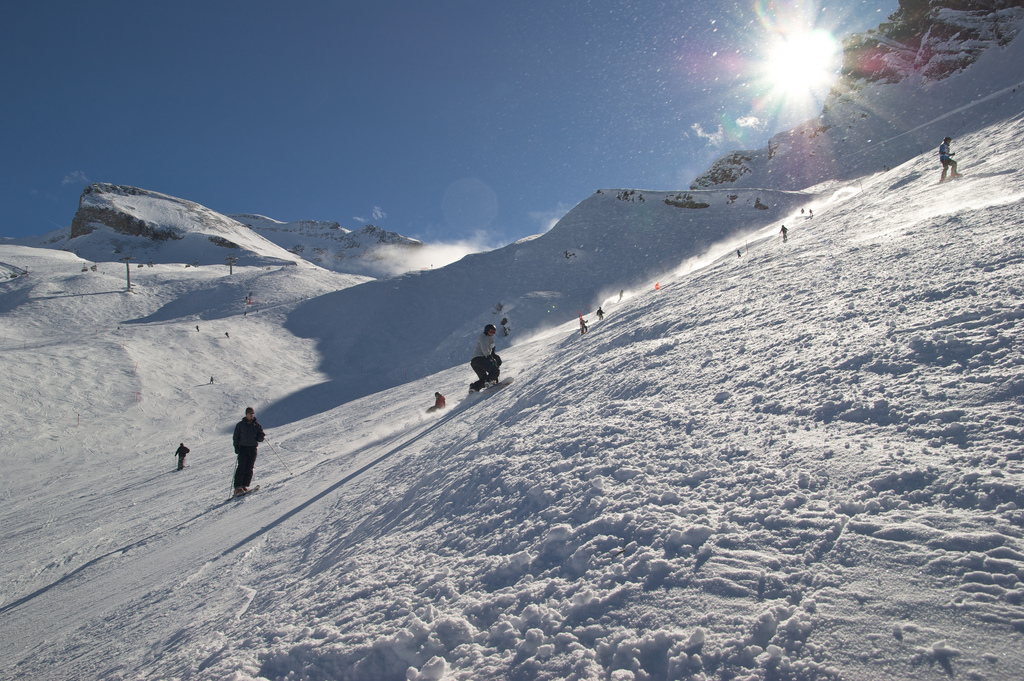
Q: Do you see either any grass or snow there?
A: Yes, there is snow.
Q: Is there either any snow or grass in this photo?
A: Yes, there is snow.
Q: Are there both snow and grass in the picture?
A: No, there is snow but no grass.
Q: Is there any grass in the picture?
A: No, there is no grass.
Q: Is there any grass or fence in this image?
A: No, there are no grass or fences.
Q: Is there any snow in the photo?
A: Yes, there is snow.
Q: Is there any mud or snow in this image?
A: Yes, there is snow.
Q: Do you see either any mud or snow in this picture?
A: Yes, there is snow.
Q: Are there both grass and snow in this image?
A: No, there is snow but no grass.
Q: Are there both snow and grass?
A: No, there is snow but no grass.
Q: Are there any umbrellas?
A: No, there are no umbrellas.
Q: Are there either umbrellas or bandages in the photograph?
A: No, there are no umbrellas or bandages.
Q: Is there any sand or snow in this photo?
A: Yes, there is snow.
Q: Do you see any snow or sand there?
A: Yes, there is snow.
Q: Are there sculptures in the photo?
A: No, there are no sculptures.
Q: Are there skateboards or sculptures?
A: No, there are no sculptures or skateboards.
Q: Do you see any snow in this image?
A: Yes, there is snow.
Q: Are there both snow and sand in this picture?
A: No, there is snow but no sand.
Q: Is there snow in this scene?
A: Yes, there is snow.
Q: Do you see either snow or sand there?
A: Yes, there is snow.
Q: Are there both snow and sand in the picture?
A: No, there is snow but no sand.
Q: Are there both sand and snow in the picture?
A: No, there is snow but no sand.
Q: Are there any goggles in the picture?
A: No, there are no goggles.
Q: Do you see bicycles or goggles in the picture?
A: No, there are no goggles or bicycles.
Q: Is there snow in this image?
A: Yes, there is snow.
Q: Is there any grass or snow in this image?
A: Yes, there is snow.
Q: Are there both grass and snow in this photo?
A: No, there is snow but no grass.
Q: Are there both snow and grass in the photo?
A: No, there is snow but no grass.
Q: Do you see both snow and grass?
A: No, there is snow but no grass.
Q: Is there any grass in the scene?
A: No, there is no grass.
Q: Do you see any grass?
A: No, there is no grass.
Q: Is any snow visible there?
A: Yes, there is snow.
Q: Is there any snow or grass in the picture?
A: Yes, there is snow.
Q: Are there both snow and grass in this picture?
A: No, there is snow but no grass.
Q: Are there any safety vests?
A: No, there are no safety vests.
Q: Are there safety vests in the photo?
A: No, there are no safety vests.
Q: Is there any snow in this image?
A: Yes, there is snow.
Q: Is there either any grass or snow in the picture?
A: Yes, there is snow.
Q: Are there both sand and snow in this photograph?
A: No, there is snow but no sand.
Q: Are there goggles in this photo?
A: No, there are no goggles.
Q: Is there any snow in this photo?
A: Yes, there is snow.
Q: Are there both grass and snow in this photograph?
A: No, there is snow but no grass.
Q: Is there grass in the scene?
A: No, there is no grass.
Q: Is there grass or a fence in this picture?
A: No, there are no grass or fences.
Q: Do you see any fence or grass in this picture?
A: No, there are no grass or fences.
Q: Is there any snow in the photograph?
A: Yes, there is snow.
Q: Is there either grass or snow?
A: Yes, there is snow.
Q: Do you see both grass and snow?
A: No, there is snow but no grass.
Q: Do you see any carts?
A: No, there are no carts.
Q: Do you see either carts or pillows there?
A: No, there are no carts or pillows.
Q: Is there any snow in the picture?
A: Yes, there is snow.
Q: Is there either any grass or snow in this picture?
A: Yes, there is snow.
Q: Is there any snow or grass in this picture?
A: Yes, there is snow.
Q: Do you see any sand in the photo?
A: No, there is no sand.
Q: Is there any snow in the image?
A: Yes, there is snow.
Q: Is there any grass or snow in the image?
A: Yes, there is snow.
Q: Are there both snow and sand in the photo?
A: No, there is snow but no sand.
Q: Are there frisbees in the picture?
A: No, there are no frisbees.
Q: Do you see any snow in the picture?
A: Yes, there is snow.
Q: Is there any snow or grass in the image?
A: Yes, there is snow.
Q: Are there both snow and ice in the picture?
A: No, there is snow but no ice.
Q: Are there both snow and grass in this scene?
A: No, there is snow but no grass.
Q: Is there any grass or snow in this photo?
A: Yes, there is snow.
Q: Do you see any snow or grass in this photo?
A: Yes, there is snow.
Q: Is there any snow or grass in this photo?
A: Yes, there is snow.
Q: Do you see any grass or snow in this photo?
A: Yes, there is snow.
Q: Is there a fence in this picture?
A: No, there are no fences.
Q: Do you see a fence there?
A: No, there are no fences.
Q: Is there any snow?
A: Yes, there is snow.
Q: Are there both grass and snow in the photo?
A: No, there is snow but no grass.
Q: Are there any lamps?
A: No, there are no lamps.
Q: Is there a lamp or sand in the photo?
A: No, there are no lamps or sand.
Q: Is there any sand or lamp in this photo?
A: No, there are no lamps or sand.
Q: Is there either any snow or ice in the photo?
A: Yes, there is snow.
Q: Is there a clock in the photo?
A: No, there are no clocks.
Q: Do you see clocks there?
A: No, there are no clocks.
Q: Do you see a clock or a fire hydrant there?
A: No, there are no clocks or fire hydrants.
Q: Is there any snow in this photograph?
A: Yes, there is snow.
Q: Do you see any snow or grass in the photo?
A: Yes, there is snow.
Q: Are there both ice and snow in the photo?
A: No, there is snow but no ice.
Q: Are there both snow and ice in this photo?
A: No, there is snow but no ice.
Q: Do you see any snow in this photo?
A: Yes, there is snow.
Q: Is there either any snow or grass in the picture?
A: Yes, there is snow.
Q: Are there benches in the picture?
A: No, there are no benches.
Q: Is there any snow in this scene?
A: Yes, there is snow.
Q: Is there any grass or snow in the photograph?
A: Yes, there is snow.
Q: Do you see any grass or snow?
A: Yes, there is snow.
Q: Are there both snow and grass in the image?
A: No, there is snow but no grass.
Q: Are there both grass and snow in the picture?
A: No, there is snow but no grass.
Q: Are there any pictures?
A: No, there are no pictures.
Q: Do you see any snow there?
A: Yes, there is snow.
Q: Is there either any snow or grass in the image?
A: Yes, there is snow.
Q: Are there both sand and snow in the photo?
A: No, there is snow but no sand.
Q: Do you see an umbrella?
A: No, there are no umbrellas.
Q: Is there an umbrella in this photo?
A: No, there are no umbrellas.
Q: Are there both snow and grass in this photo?
A: No, there is snow but no grass.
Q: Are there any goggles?
A: No, there are no goggles.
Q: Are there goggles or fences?
A: No, there are no goggles or fences.